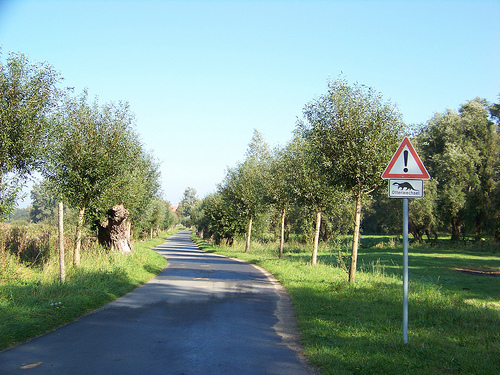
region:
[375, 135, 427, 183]
red white and black sign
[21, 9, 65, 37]
white clouds in blue sky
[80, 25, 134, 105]
white clouds in blue sky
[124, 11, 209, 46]
white clouds in blue sky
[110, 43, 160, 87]
white clouds in blue sky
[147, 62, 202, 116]
white clouds in blue sky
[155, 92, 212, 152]
white clouds in blue sky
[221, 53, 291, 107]
white clouds in blue sky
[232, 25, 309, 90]
white clouds in blue sky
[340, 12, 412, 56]
white clouds in blue sky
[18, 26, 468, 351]
road in near the trees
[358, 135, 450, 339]
a sign for traffic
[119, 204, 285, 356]
this road looks long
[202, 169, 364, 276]
trees along the road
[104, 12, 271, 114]
the sky above the ground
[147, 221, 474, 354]
sun shining in the area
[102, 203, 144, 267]
a tree stump near the road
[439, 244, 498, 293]
some kind of object near the road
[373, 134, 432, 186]
this is a caution sign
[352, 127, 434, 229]
this sign designates an animal crossing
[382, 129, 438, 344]
TRIANGLE SIGN ON POLE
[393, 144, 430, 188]
EXCLAMATION MARK ON SIGN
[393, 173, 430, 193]
BRONTOSAURUS ON SIGN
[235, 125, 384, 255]
TREES ON SIDE OF ROAD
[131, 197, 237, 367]
SMALL PAVED ROAD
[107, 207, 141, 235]
LARGE TREE STUMP ON LEFT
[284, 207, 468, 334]
SUN SHINING ON GRASS THOUGH TREES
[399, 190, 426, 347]
GRAY METAL POLE UNDER SIGN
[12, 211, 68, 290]
TALL GREEN GRASS ON LEFT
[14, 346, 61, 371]
YELLOW SPOT ON ROAD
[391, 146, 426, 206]
red white and black street sign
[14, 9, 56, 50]
white clouds in blue sky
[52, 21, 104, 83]
white clouds in blue sky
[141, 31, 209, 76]
white clouds in blue sky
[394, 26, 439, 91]
white clouds in blue sky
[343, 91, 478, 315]
This is a street sign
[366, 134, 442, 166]
The sign has an exclamation mark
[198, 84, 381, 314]
These are old trees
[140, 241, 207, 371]
This is a long path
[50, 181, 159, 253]
This is a tree stump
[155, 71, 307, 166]
There are no clouds in the sky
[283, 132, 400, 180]
The leaves are light green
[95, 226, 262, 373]
There are no animals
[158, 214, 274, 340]
There are no people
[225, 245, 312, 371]
The path is empty